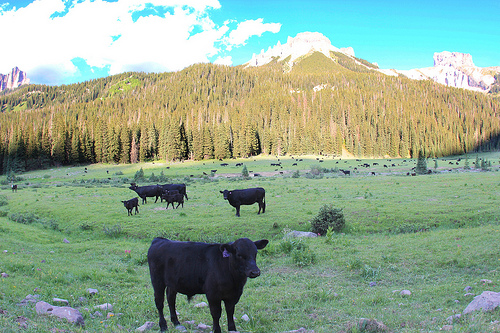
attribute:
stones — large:
[449, 276, 491, 331]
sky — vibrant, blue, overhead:
[266, 7, 498, 49]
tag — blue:
[222, 250, 229, 260]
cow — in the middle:
[220, 186, 268, 216]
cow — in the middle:
[219, 184, 272, 214]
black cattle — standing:
[139, 228, 284, 330]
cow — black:
[85, 201, 303, 331]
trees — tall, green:
[11, 59, 488, 160]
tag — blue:
[220, 249, 233, 260]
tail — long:
[260, 191, 275, 216]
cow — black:
[118, 192, 144, 222]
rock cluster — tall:
[0, 63, 35, 94]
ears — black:
[221, 238, 233, 258]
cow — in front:
[86, 215, 316, 307]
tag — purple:
[220, 240, 238, 258]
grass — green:
[351, 187, 472, 231]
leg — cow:
[208, 294, 223, 331]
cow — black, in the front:
[147, 231, 271, 331]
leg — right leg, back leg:
[166, 294, 193, 330]